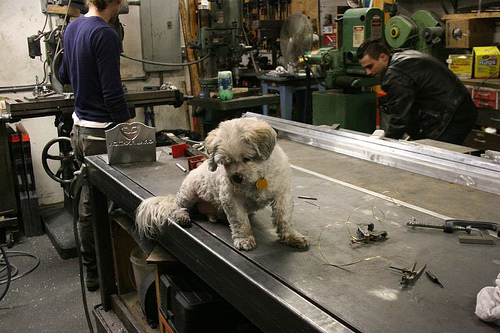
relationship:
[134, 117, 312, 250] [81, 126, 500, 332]
dog on table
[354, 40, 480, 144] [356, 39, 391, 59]
man has hair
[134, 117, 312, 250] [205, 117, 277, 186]
dog has a head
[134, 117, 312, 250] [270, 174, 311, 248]
dog has leg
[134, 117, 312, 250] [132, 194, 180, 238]
dog has tail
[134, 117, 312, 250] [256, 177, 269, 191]
dog has tag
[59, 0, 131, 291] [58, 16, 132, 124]
person has shirt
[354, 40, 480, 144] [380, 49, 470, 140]
man has jacket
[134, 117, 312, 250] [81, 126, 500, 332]
dog sitting on table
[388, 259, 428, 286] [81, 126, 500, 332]
tool on table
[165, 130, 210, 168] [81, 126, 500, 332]
tool on table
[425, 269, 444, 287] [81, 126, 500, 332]
tool on table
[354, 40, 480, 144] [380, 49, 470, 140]
man wearing jacket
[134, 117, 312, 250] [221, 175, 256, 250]
dog has leg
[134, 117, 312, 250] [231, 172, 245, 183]
dog has nose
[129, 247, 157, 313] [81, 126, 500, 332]
bucket under table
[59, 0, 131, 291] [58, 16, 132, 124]
person wearing shirt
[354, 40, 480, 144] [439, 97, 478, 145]
man wearing pants